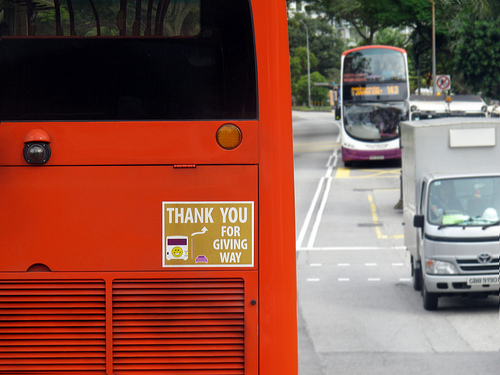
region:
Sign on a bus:
[146, 189, 270, 294]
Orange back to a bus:
[20, 104, 299, 373]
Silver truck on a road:
[388, 103, 498, 300]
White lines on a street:
[306, 188, 401, 364]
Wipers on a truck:
[422, 200, 498, 268]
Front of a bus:
[334, 38, 411, 154]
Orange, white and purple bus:
[339, 35, 426, 188]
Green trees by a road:
[288, 5, 499, 113]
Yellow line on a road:
[318, 156, 415, 253]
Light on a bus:
[192, 123, 279, 168]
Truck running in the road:
[391, 108, 499, 320]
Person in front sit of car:
[431, 181, 476, 228]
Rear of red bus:
[0, 0, 307, 372]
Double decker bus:
[326, 33, 419, 173]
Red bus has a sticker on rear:
[151, 191, 261, 276]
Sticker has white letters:
[155, 192, 262, 276]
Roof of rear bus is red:
[336, 40, 411, 78]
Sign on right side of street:
[429, 69, 456, 94]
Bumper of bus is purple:
[336, 145, 404, 166]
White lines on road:
[296, 145, 349, 260]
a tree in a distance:
[295, 65, 330, 107]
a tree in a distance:
[293, 44, 316, 74]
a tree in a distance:
[286, 52, 303, 99]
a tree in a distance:
[296, 7, 324, 47]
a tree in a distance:
[315, 31, 342, 66]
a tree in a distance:
[328, 0, 388, 41]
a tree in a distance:
[451, 17, 497, 87]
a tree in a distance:
[413, 30, 453, 97]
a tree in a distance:
[441, 3, 493, 22]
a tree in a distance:
[295, 15, 335, 38]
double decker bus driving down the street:
[314, 37, 450, 189]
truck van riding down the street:
[323, 86, 497, 321]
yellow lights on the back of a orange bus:
[196, 97, 301, 155]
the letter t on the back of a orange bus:
[131, 176, 290, 302]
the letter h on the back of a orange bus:
[135, 176, 287, 293]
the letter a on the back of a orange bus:
[138, 160, 290, 284]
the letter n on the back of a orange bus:
[150, 177, 267, 306]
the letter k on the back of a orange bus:
[125, 181, 267, 305]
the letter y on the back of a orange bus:
[110, 161, 286, 299]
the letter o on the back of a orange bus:
[136, 186, 269, 312]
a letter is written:
[162, 204, 177, 226]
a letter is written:
[172, 205, 184, 226]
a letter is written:
[183, 205, 193, 226]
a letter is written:
[191, 205, 203, 226]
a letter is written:
[203, 203, 214, 228]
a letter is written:
[218, 205, 230, 224]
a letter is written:
[225, 207, 240, 227]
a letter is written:
[236, 205, 250, 223]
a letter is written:
[218, 225, 227, 237]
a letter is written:
[225, 225, 236, 236]